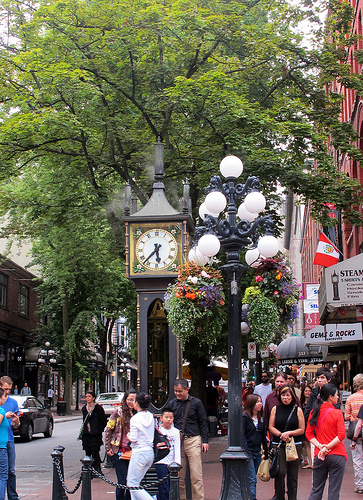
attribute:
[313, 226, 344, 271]
flag — red, white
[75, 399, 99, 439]
bag — hippie, green, white, alpaca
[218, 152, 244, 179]
globe — white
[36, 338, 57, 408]
lamppost — identical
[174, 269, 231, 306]
flower — arranged, hanging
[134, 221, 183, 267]
clock — lacking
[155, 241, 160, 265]
hand — second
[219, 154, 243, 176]
globe — frosted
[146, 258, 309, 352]
plants — flowering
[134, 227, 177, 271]
clock — large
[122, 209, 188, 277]
clock — matching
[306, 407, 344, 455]
shirt — long sleeve, red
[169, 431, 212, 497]
pants — khaki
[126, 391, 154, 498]
person — wearing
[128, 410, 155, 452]
jacket — white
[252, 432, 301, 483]
brown bag — paper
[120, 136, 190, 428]
tower — metal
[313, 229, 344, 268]
flag — hanging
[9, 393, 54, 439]
black car — driving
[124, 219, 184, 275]
clock — ornated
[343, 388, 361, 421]
shirt — orange, white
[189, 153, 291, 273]
pole — black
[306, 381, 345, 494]
woman — wearing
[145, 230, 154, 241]
numeral — roman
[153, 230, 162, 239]
numeral — roman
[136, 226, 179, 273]
numerals — roman